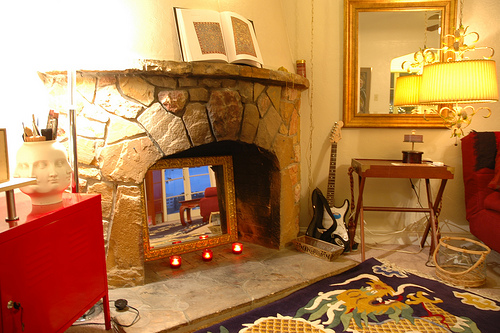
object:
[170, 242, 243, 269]
candles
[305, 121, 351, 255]
guitar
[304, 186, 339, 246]
strap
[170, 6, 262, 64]
book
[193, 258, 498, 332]
carpet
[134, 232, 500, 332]
floor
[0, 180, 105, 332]
table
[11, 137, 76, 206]
vase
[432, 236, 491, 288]
basket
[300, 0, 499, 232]
wall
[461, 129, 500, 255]
couch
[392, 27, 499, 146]
light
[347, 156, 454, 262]
table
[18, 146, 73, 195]
face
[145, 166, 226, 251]
mirror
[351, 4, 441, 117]
mirror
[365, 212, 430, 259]
wire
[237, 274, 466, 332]
dragon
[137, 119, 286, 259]
fireplace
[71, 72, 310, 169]
stone